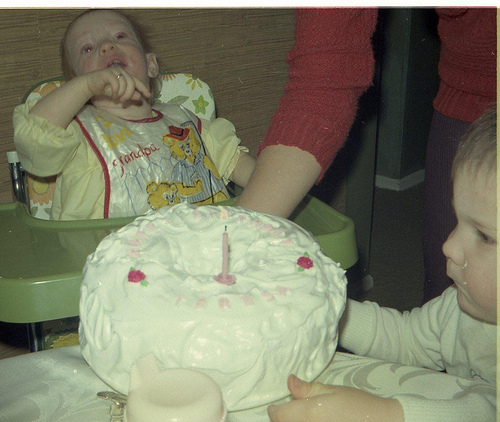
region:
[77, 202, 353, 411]
A cake with white frosting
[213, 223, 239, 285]
A pink candle on the cake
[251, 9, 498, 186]
A person wearing a red sweater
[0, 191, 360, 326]
A green tray on a high chair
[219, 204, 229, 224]
Flame on the pink candle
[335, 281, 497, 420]
A child wearing a white sweatshirt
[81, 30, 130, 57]
A baby with red eyes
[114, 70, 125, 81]
A baby with a gold ring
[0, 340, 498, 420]
A white patterned tablecloth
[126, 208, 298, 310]
Pink lettering on the cake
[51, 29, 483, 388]
two babies in picture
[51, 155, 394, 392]
this is a birthday cake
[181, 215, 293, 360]
the candle is pink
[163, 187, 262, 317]
there is one candle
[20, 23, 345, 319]
the high chair is green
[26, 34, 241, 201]
this baby has a bib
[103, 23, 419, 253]
the adult has a red sweater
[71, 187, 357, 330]
the cake is white frosted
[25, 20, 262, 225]
the baby wears yellow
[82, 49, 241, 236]
the bib has bears on it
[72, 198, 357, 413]
Baby touching cake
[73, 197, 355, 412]
What a beautiful cake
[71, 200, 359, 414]
You mean just 1 candle ?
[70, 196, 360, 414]
Is this mine?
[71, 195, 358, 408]
Ahhh is this for me?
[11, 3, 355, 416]
Hey is that mines too?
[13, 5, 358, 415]
Where's mine?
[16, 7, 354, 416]
Hey! I am 1 as well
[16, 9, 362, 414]
That is both of ours Right?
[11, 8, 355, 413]
Am I getting a piece of that?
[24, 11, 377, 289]
a baby in a high chair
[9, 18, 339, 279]
a baby looking up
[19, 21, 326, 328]
a baby with a bib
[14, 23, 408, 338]
baby wearing a bib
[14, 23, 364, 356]
a high chair with a baby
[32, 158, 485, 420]
a white cake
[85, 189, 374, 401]
a white birthday cake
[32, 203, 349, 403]
a cake with a candle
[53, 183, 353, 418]
a white cake with a candle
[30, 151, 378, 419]
a birthday cake with candle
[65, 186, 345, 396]
cake with white icing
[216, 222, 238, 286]
candle of cake with white icing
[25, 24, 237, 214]
baby sitting in high chair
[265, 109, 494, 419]
child touching white cake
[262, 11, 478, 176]
red shirt of person holding cake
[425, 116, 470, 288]
purple pants of person holding cake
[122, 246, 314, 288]
two red decorations on top of cake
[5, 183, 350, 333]
green tray on high chair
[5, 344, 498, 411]
tablecloth on table underneath cake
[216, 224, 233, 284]
one pink candle on cake